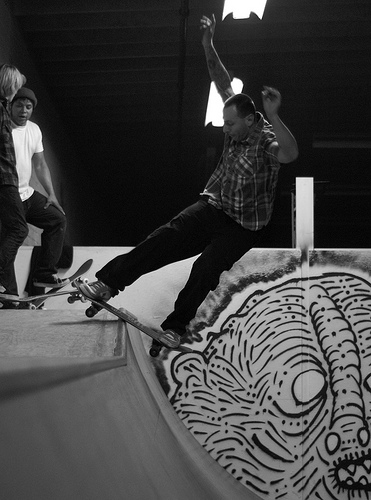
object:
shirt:
[7, 115, 44, 204]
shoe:
[158, 327, 181, 347]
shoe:
[79, 279, 115, 301]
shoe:
[33, 273, 69, 287]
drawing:
[215, 291, 369, 445]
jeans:
[95, 192, 247, 330]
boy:
[11, 87, 74, 290]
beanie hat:
[12, 86, 35, 99]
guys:
[10, 82, 73, 305]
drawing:
[169, 270, 369, 498]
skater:
[64, 7, 295, 357]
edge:
[116, 299, 157, 388]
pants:
[82, 190, 268, 334]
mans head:
[220, 92, 258, 142]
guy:
[81, 11, 302, 350]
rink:
[0, 246, 370, 498]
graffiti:
[266, 280, 351, 368]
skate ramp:
[0, 310, 278, 498]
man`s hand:
[43, 195, 64, 219]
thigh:
[25, 191, 65, 229]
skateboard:
[67, 276, 194, 358]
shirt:
[206, 120, 304, 237]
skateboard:
[1, 257, 93, 310]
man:
[0, 59, 31, 308]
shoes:
[0, 274, 19, 308]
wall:
[10, 247, 369, 497]